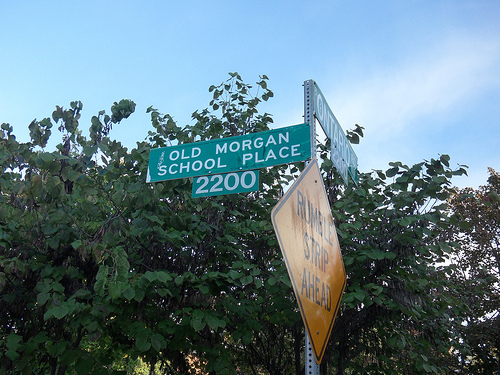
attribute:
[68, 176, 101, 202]
leaf — green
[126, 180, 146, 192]
leaf — green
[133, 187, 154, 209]
leaf — green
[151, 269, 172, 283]
leaf — green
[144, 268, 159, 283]
leaf — green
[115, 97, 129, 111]
leaf — green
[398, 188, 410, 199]
leaf — green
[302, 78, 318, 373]
pole — metal 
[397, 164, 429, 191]
leaf — green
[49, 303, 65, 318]
leaf — green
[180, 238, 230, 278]
leaf — green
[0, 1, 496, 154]
sky — blue